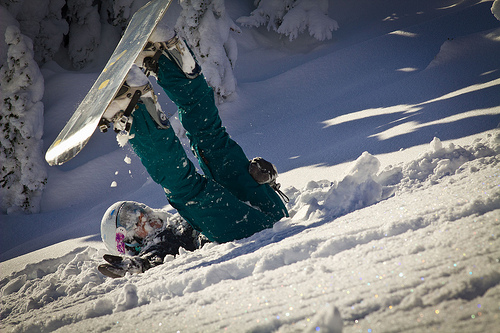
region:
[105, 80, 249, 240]
A man on snow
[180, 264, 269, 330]
A field covered by snow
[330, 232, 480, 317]
A field covered by snow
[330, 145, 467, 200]
A field covered by snow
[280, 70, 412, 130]
A field covered by snow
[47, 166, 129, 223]
A field covered by snow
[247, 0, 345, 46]
A tree branch covered by snow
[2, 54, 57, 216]
A tree branch covered by snow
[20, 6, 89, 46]
A tree branch covered by snow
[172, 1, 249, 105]
A tree branch covered by snow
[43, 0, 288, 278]
the person is snowboarding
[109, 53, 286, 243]
person is wearing turquoise pants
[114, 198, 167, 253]
person has ski goggles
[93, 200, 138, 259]
person is wearing white hat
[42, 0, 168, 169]
snow board has black bottom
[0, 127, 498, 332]
snow has tracks in it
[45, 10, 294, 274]
snowboarder crashed into snow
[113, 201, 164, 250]
snow ontop of face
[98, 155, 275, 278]
person wearing black ski gloves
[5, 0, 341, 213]
snow covered trees behind person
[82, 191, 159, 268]
skier has white helmet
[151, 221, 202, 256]
snowboarder has dark coat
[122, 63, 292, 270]
boarder has green pants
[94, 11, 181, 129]
boarder has grey boots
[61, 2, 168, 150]
black and yellow board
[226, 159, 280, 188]
boarder has dark gloves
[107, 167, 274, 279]
boarder is on back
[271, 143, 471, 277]
tracks in white snow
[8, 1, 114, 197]
trees are behind boarder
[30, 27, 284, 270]
snowboarder is fallen in snow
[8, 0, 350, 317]
A person playing with snowboard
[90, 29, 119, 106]
Bottom of the snowboard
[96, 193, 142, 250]
A person wearing white color helmet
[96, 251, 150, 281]
A person wearing glove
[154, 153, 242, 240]
A person wearing snow suit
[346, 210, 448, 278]
White color snow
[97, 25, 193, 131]
A person wearing pair of shoes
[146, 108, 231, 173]
Legs of the person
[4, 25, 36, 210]
Tree covered with snow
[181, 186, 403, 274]
Shadow of the snowboard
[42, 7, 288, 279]
snowboarder falling on the ground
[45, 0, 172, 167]
black and yellow snowboard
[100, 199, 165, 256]
white helmet on head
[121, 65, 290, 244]
green snow pants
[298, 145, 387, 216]
clump of white snow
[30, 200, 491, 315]
tracks in the snow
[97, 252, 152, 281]
black mitten on hand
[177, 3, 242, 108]
snow weighing down pine branches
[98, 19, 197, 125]
white ski boots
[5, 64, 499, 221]
shadow cast by trees